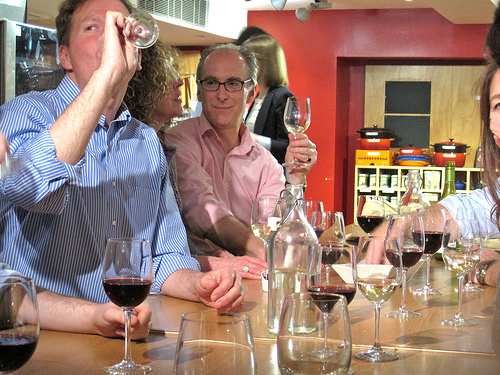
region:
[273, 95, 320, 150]
clear wine glass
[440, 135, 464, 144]
black lid on cooking pot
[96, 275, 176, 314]
red wine in glass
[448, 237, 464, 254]
shine reflection on glass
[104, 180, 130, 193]
white button on blue shirt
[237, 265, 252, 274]
silver ring on finger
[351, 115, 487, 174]
cooking utensils on shelf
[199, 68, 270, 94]
black rimmed eye glasses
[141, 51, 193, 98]
curly short blond hair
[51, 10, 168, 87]
man drinking from glass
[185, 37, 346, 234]
balding man wearing glasses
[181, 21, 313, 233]
bald man in a pink shirt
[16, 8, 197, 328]
man wearing a blue and white shirt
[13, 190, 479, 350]
half full wine glasses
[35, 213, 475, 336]
wine glasses filled with red wine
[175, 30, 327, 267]
man who finished his wine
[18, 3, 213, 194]
man drinking red wine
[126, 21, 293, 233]
man listening to a woman talk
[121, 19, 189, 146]
woman with curly blonde hair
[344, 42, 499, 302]
woman reaching for food in a white dish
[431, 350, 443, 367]
part of a table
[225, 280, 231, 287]
part of a finger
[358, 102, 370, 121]
part of a wall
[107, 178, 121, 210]
part of a shirt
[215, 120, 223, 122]
part of a chin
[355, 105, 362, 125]
edge of a wall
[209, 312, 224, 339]
edge of a cup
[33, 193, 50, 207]
part of an elbow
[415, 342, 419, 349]
part of a table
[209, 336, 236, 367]
part of a glass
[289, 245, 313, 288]
part of a bottle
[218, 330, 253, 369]
part of a glass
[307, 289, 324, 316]
edge of a glass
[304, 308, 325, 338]
part of a glass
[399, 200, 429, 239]
part of a glass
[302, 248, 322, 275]
part of a glass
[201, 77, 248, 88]
The eyeglasses the man is wearing.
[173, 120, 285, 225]
The pink shirt the man is wearing.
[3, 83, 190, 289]
The striped shirt the man is wearing.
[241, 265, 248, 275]
The ring on the lady's finger.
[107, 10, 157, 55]
The glass the man is drinking from.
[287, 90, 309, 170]
The glass in the man's hand.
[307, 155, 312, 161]
The ring on the man's finger.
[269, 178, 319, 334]
The glass bottle in the center of the table.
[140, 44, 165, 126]
The curly hair of the woman.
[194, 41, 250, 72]
The bald head of the man.